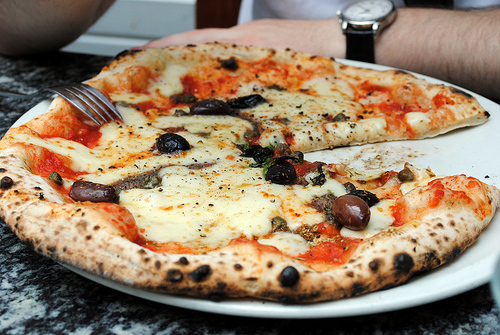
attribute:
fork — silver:
[1, 78, 123, 125]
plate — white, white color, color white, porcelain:
[53, 57, 499, 318]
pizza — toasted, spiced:
[2, 41, 499, 303]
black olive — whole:
[332, 194, 371, 230]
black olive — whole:
[69, 178, 114, 204]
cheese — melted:
[21, 60, 438, 255]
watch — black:
[334, 0, 398, 65]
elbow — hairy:
[1, 1, 114, 58]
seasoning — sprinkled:
[99, 87, 388, 249]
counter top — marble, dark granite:
[1, 48, 498, 334]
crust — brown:
[1, 41, 499, 303]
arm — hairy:
[303, 4, 498, 106]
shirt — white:
[233, 1, 499, 33]